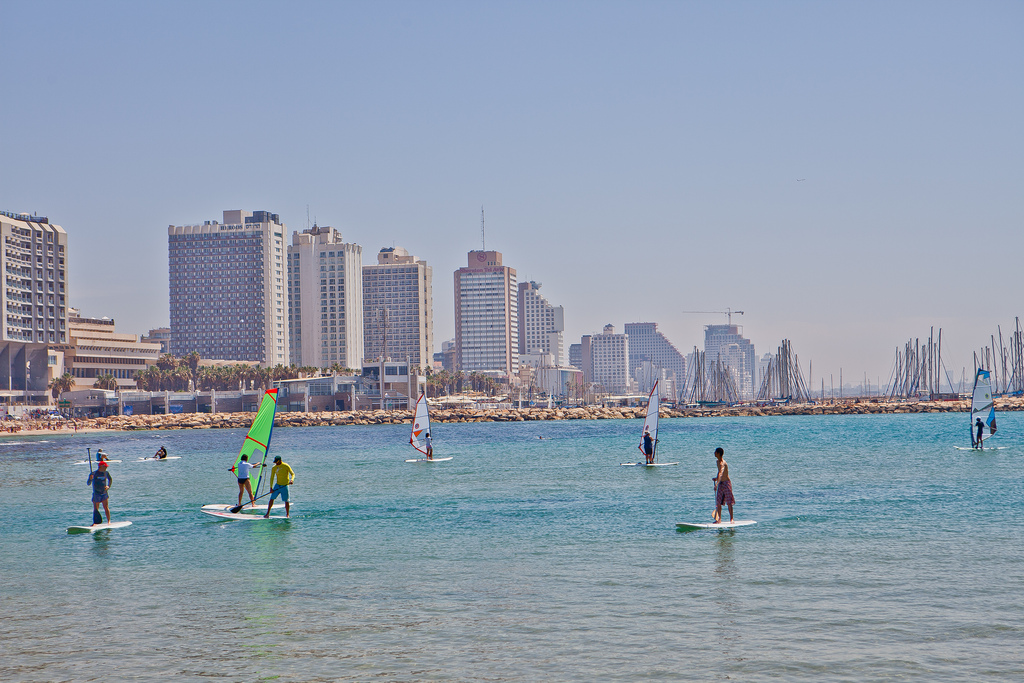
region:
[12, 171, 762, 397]
Buildings behind the ocean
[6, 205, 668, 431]
Buildings along the coast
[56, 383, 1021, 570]
People on the water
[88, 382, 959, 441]
Rocks along the ocean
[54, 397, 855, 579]
People surfing in the water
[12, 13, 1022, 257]
Sky above buildings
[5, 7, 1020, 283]
Sky overlooking the water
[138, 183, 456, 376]
Tall buildings beside each other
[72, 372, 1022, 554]
People randomly placed in water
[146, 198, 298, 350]
a tall grey building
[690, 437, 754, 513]
a person on a surfboard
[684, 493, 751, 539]
a white color surfboard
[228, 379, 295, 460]
a green sail on a surfboard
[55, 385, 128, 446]
sand in the distance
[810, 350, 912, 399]
a bunch of tall buildings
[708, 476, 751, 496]
shorts that are black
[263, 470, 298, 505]
the body of a person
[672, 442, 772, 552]
surf paddler in the water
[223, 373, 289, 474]
green sail on a surfboard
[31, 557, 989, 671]
ocean water where people are paddling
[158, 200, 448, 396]
buildings on the coastline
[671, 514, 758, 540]
surfboard in the water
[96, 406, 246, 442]
rocks along a coastline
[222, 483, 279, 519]
paddle in the hands of a man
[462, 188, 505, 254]
top of a tower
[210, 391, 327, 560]
people playing on the water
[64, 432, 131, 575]
people playing on the water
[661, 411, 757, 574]
people playing on the water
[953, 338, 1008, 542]
people playing on the water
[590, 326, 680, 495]
people playing on the water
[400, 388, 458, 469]
people playing on the water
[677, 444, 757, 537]
person standing on a surfboard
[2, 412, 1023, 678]
blue body of water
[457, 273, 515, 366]
several windows on the side of the building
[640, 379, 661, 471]
sail is attached to the board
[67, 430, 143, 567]
person is riding a stand up paddle board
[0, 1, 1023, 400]
light blue sky with no clouds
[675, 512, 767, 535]
board is laying on the water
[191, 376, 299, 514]
A person on a sailboard with a green and red sail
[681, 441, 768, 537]
A person in purple shorts standing on a board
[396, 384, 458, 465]
A person on a sailboard with a blue and red sail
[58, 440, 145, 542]
A person in a ret cap and blue short standing on a board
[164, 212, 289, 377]
A building in a city.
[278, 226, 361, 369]
A building in a city.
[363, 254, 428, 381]
A building in a city.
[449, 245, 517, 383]
A building in a city.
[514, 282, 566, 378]
A building in a city.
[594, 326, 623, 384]
A building in a city.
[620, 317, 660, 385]
A building in a city.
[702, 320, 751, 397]
A building in a city.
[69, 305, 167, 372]
A building in a city.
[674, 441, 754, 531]
human floats on water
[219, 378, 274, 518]
human floats on water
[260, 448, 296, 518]
human floats on water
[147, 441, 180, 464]
human floats on water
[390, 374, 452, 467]
human floats on water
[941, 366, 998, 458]
human floats on water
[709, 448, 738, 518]
human rides on top of paddleboard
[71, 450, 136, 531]
human rides on top of paddleboard